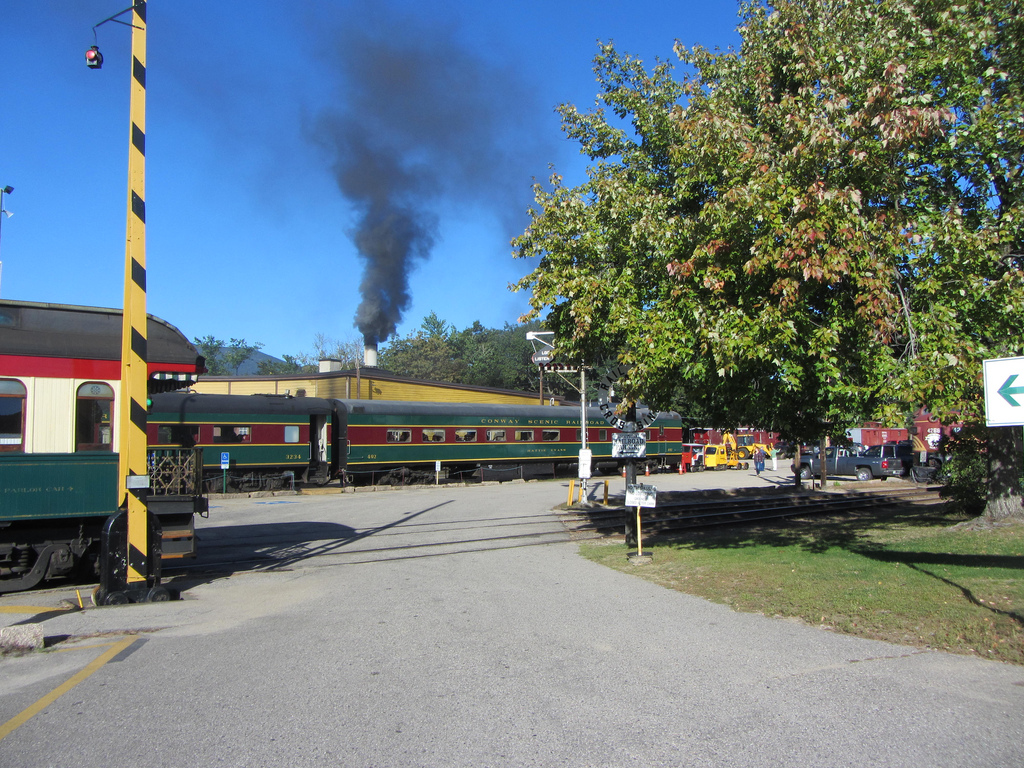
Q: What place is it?
A: It is a road.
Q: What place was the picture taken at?
A: It was taken at the road.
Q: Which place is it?
A: It is a road.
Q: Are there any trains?
A: Yes, there is a train.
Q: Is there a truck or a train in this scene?
A: Yes, there is a train.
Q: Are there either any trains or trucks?
A: Yes, there is a train.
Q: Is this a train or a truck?
A: This is a train.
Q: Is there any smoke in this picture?
A: Yes, there is smoke.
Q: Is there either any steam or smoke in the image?
A: Yes, there is smoke.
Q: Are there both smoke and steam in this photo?
A: No, there is smoke but no steam.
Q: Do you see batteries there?
A: No, there are no batteries.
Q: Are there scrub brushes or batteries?
A: No, there are no batteries or scrub brushes.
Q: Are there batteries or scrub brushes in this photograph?
A: No, there are no batteries or scrub brushes.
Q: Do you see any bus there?
A: No, there are no buses.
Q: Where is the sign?
A: The sign is on the grass.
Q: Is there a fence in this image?
A: No, there are no fences.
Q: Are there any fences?
A: No, there are no fences.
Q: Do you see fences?
A: No, there are no fences.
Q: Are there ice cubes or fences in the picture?
A: No, there are no fences or ice cubes.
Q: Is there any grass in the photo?
A: Yes, there is grass.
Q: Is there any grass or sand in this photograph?
A: Yes, there is grass.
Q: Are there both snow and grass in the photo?
A: No, there is grass but no snow.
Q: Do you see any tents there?
A: No, there are no tents.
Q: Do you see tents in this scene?
A: No, there are no tents.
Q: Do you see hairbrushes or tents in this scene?
A: No, there are no tents or hairbrushes.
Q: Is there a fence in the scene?
A: No, there are no fences.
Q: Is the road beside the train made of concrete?
A: Yes, the road is made of concrete.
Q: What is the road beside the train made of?
A: The road is made of cement.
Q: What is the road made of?
A: The road is made of concrete.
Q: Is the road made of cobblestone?
A: No, the road is made of concrete.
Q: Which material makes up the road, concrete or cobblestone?
A: The road is made of concrete.